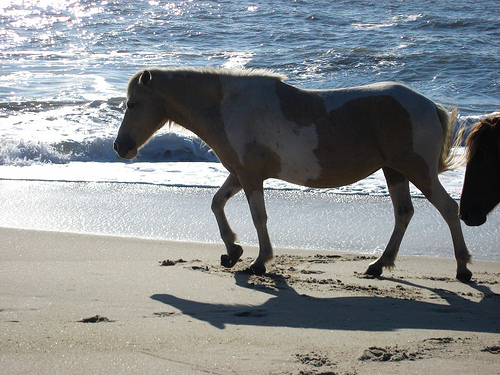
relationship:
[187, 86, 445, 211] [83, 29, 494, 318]
hair of horse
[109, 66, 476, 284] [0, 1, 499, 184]
horse walking near lake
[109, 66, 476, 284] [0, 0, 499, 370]
horse walking on beach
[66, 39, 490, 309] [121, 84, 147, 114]
horse has eye